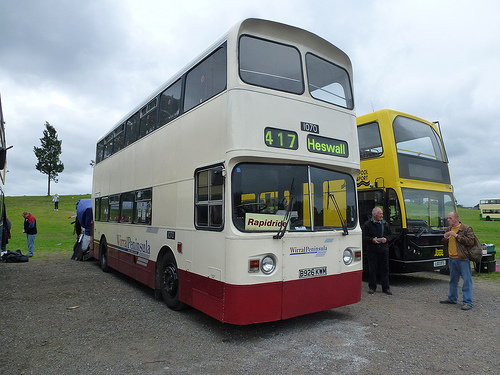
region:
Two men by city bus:
[366, 202, 496, 309]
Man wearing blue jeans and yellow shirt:
[439, 208, 485, 323]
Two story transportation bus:
[51, 13, 367, 325]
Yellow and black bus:
[356, 106, 458, 283]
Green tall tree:
[20, 116, 73, 213]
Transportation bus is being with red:
[109, 5, 371, 338]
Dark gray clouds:
[28, 13, 124, 85]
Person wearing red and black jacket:
[20, 206, 48, 253]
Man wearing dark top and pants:
[360, 206, 398, 300]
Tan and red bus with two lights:
[88, 15, 362, 332]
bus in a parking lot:
[51, 5, 367, 311]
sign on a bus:
[237, 112, 363, 160]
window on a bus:
[245, 30, 303, 98]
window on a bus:
[310, 47, 360, 108]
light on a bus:
[235, 236, 275, 278]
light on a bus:
[338, 245, 368, 270]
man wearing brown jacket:
[426, 195, 483, 317]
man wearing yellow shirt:
[435, 208, 480, 320]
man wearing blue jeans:
[440, 206, 482, 317]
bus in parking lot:
[372, 101, 457, 196]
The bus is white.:
[65, 45, 382, 326]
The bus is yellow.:
[358, 102, 468, 282]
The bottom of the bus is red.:
[75, 235, 379, 329]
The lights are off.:
[247, 248, 364, 270]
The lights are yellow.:
[255, 123, 356, 162]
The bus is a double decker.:
[65, 9, 379, 340]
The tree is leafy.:
[28, 116, 70, 201]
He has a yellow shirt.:
[435, 227, 476, 259]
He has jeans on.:
[435, 259, 485, 301]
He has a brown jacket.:
[432, 218, 496, 257]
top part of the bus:
[223, 23, 378, 113]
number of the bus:
[252, 110, 318, 157]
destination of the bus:
[303, 135, 370, 171]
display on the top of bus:
[244, 115, 380, 167]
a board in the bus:
[231, 203, 302, 248]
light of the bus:
[241, 240, 308, 305]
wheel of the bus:
[144, 238, 222, 313]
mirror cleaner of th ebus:
[305, 178, 368, 245]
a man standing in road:
[429, 195, 496, 319]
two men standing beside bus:
[368, 187, 492, 294]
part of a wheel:
[150, 289, 160, 296]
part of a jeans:
[463, 279, 467, 285]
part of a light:
[258, 260, 283, 274]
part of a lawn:
[73, 230, 93, 240]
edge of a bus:
[221, 250, 233, 265]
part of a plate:
[313, 275, 318, 283]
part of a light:
[264, 271, 271, 283]